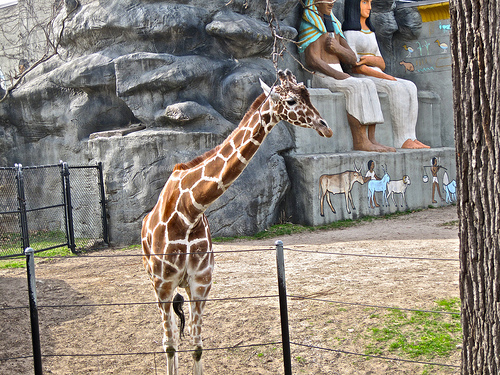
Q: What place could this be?
A: It is a pen.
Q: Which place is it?
A: It is a pen.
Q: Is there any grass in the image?
A: Yes, there is grass.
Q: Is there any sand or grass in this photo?
A: Yes, there is grass.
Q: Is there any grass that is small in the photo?
A: Yes, there is small grass.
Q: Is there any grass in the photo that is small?
A: Yes, there is grass that is small.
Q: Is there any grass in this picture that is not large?
A: Yes, there is small grass.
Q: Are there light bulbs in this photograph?
A: No, there are no light bulbs.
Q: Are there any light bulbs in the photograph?
A: No, there are no light bulbs.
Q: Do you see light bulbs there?
A: No, there are no light bulbs.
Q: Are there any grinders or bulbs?
A: No, there are no bulbs or grinders.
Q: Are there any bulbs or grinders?
A: No, there are no bulbs or grinders.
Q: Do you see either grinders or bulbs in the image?
A: No, there are no bulbs or grinders.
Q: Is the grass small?
A: Yes, the grass is small.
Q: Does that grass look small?
A: Yes, the grass is small.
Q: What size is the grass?
A: The grass is small.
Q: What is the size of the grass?
A: The grass is small.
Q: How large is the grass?
A: The grass is small.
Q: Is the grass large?
A: No, the grass is small.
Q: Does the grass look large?
A: No, the grass is small.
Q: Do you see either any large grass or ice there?
A: No, there is grass but it is small.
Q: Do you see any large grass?
A: No, there is grass but it is small.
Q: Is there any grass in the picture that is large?
A: No, there is grass but it is small.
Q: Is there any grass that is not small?
A: No, there is grass but it is small.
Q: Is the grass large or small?
A: The grass is small.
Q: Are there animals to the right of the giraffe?
A: Yes, there is an animal to the right of the giraffe.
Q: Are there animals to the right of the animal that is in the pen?
A: Yes, there is an animal to the right of the giraffe.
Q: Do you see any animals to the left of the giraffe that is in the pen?
A: No, the animal is to the right of the giraffe.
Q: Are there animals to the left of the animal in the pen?
A: No, the animal is to the right of the giraffe.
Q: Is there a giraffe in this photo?
A: Yes, there is a giraffe.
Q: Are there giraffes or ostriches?
A: Yes, there is a giraffe.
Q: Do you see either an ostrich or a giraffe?
A: Yes, there is a giraffe.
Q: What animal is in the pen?
A: The giraffe is in the pen.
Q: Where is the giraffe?
A: The giraffe is in the pen.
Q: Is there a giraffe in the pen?
A: Yes, there is a giraffe in the pen.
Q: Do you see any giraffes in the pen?
A: Yes, there is a giraffe in the pen.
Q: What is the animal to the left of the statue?
A: The animal is a giraffe.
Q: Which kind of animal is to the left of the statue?
A: The animal is a giraffe.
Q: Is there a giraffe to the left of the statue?
A: Yes, there is a giraffe to the left of the statue.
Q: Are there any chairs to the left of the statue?
A: No, there is a giraffe to the left of the statue.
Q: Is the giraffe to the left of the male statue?
A: Yes, the giraffe is to the left of the statue.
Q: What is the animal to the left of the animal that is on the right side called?
A: The animal is a giraffe.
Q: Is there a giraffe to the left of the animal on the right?
A: Yes, there is a giraffe to the left of the animal.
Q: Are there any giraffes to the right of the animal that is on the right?
A: No, the giraffe is to the left of the animal.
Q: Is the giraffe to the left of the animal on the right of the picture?
A: Yes, the giraffe is to the left of the animal.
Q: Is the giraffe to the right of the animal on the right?
A: No, the giraffe is to the left of the animal.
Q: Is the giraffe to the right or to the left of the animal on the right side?
A: The giraffe is to the left of the animal.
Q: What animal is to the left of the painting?
A: The animal is a giraffe.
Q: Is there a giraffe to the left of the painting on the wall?
A: Yes, there is a giraffe to the left of the painting.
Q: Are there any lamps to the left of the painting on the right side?
A: No, there is a giraffe to the left of the painting.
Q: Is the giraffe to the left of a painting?
A: Yes, the giraffe is to the left of a painting.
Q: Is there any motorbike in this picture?
A: No, there are no motorcycles.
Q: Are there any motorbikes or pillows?
A: No, there are no motorbikes or pillows.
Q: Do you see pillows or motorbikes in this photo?
A: No, there are no motorbikes or pillows.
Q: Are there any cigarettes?
A: No, there are no cigarettes.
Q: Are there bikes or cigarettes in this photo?
A: No, there are no cigarettes or bikes.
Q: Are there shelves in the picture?
A: No, there are no shelves.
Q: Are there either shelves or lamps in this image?
A: No, there are no shelves or lamps.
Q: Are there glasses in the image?
A: No, there are no glasses.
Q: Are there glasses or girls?
A: No, there are no glasses or girls.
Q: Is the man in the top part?
A: Yes, the man is in the top of the image.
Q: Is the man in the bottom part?
A: No, the man is in the top of the image.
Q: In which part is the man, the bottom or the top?
A: The man is in the top of the image.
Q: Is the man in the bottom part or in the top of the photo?
A: The man is in the top of the image.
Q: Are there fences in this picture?
A: Yes, there is a fence.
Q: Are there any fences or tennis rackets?
A: Yes, there is a fence.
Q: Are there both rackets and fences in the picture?
A: No, there is a fence but no rackets.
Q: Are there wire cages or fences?
A: Yes, there is a wire fence.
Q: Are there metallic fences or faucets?
A: Yes, there is a metal fence.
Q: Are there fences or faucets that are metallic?
A: Yes, the fence is metallic.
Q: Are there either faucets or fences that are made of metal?
A: Yes, the fence is made of metal.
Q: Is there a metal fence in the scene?
A: Yes, there is a metal fence.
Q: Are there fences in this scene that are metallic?
A: Yes, there is a fence that is metallic.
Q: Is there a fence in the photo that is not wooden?
A: Yes, there is a metallic fence.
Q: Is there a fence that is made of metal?
A: Yes, there is a fence that is made of metal.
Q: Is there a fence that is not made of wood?
A: Yes, there is a fence that is made of metal.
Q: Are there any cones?
A: No, there are no cones.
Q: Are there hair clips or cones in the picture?
A: No, there are no cones or hair clips.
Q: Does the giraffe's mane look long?
A: Yes, the mane is long.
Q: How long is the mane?
A: The mane is long.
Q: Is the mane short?
A: No, the mane is long.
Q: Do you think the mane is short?
A: No, the mane is long.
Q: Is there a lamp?
A: No, there are no lamps.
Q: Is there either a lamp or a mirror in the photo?
A: No, there are no lamps or mirrors.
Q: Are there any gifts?
A: No, there are no gifts.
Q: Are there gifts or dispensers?
A: No, there are no gifts or dispensers.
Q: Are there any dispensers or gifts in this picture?
A: No, there are no gifts or dispensers.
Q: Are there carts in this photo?
A: No, there are no carts.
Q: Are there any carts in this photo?
A: No, there are no carts.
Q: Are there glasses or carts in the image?
A: No, there are no carts or glasses.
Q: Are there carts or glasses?
A: No, there are no carts or glasses.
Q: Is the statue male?
A: Yes, the statue is male.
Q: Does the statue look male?
A: Yes, the statue is male.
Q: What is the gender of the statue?
A: The statue is male.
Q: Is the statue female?
A: No, the statue is male.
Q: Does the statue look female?
A: No, the statue is male.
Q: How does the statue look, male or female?
A: The statue is male.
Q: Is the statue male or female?
A: The statue is male.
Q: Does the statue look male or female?
A: The statue is male.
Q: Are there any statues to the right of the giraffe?
A: Yes, there is a statue to the right of the giraffe.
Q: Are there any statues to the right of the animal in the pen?
A: Yes, there is a statue to the right of the giraffe.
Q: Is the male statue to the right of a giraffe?
A: Yes, the statue is to the right of a giraffe.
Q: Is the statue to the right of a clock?
A: No, the statue is to the right of a giraffe.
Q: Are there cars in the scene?
A: No, there are no cars.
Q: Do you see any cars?
A: No, there are no cars.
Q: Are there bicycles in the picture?
A: No, there are no bicycles.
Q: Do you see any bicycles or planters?
A: No, there are no bicycles or planters.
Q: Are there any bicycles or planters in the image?
A: No, there are no bicycles or planters.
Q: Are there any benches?
A: No, there are no benches.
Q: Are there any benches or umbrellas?
A: No, there are no benches or umbrellas.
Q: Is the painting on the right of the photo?
A: Yes, the painting is on the right of the image.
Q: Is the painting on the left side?
A: No, the painting is on the right of the image.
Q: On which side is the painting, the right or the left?
A: The painting is on the right of the image.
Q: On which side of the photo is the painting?
A: The painting is on the right of the image.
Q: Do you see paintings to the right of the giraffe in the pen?
A: Yes, there is a painting to the right of the giraffe.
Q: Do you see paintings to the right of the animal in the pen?
A: Yes, there is a painting to the right of the giraffe.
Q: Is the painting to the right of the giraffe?
A: Yes, the painting is to the right of the giraffe.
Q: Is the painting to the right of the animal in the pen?
A: Yes, the painting is to the right of the giraffe.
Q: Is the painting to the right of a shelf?
A: No, the painting is to the right of the giraffe.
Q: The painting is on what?
A: The painting is on the wall.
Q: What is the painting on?
A: The painting is on the wall.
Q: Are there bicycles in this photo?
A: No, there are no bicycles.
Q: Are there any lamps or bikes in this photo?
A: No, there are no bikes or lamps.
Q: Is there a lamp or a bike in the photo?
A: No, there are no bikes or lamps.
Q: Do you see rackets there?
A: No, there are no rackets.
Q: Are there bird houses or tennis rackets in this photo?
A: No, there are no tennis rackets or bird houses.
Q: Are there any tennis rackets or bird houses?
A: No, there are no tennis rackets or bird houses.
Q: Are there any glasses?
A: No, there are no glasses.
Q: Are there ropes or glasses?
A: No, there are no glasses or ropes.